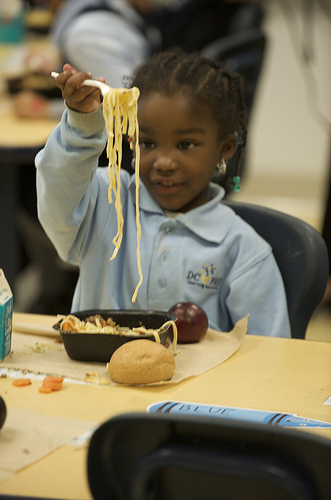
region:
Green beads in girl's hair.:
[222, 173, 244, 195]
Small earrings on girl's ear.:
[215, 156, 233, 179]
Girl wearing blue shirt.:
[158, 232, 272, 327]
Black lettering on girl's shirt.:
[187, 257, 229, 300]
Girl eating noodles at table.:
[97, 81, 151, 298]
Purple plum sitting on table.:
[167, 298, 213, 348]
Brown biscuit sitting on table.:
[107, 335, 183, 398]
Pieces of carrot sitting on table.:
[12, 371, 80, 402]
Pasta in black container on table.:
[74, 308, 159, 357]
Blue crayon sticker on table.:
[145, 390, 319, 435]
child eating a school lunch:
[22, 32, 258, 381]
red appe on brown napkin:
[167, 298, 213, 345]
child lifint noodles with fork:
[95, 65, 174, 288]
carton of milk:
[2, 271, 25, 360]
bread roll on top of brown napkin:
[110, 333, 178, 392]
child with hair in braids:
[127, 44, 259, 223]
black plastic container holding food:
[53, 292, 183, 355]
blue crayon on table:
[144, 394, 322, 427]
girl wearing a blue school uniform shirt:
[37, 124, 279, 315]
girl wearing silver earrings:
[200, 154, 236, 184]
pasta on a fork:
[101, 84, 142, 309]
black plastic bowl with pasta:
[52, 304, 175, 359]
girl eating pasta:
[48, 43, 292, 341]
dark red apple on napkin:
[166, 302, 206, 345]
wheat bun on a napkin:
[106, 339, 173, 382]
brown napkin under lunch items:
[0, 315, 249, 390]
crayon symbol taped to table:
[147, 397, 329, 429]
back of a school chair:
[90, 410, 327, 498]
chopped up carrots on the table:
[12, 373, 64, 398]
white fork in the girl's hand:
[48, 69, 136, 106]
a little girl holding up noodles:
[28, 49, 295, 351]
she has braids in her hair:
[113, 52, 250, 208]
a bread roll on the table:
[105, 336, 178, 385]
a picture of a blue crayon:
[142, 392, 328, 435]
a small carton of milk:
[0, 264, 16, 360]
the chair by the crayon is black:
[84, 410, 329, 499]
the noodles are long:
[97, 84, 148, 303]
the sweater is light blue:
[24, 105, 293, 340]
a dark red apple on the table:
[164, 298, 211, 343]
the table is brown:
[0, 304, 330, 498]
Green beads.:
[232, 177, 240, 190]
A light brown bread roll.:
[106, 338, 175, 383]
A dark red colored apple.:
[168, 300, 209, 342]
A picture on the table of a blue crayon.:
[146, 399, 326, 429]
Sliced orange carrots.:
[13, 371, 64, 392]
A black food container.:
[52, 309, 176, 363]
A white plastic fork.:
[50, 67, 139, 104]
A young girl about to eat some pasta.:
[32, 54, 292, 393]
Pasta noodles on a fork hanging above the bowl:
[45, 68, 151, 302]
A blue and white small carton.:
[0, 268, 13, 362]